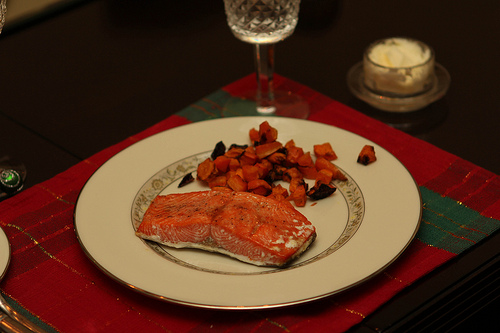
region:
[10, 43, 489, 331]
a placemat on the table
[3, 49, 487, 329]
the placemat is red and green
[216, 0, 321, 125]
a stemware glass on the placemat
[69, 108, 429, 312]
a plate on the placemat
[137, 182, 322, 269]
salmon on the plate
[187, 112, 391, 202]
orange vegetables on the plate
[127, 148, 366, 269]
flowers around the plate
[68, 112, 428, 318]
the plate has a gold rim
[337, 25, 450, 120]
a butter dish by the placemat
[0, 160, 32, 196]
a green mark on the placemat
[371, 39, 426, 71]
butter in the butter dish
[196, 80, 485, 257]
a green stripe on the placemat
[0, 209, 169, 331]
a gold stripe on the placemat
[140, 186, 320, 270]
the salmon is orange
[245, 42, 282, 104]
a stem on the glass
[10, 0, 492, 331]
the table is brown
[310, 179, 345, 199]
a black piece of squash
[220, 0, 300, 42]
a pattern on the glass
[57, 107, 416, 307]
the plate is round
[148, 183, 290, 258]
lines on the salmon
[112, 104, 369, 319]
food on a plate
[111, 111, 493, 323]
food on a white plate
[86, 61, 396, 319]
a plate on a table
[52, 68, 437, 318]
a white plate on a table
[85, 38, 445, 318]
a table with a white plate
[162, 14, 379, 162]
a glass on a table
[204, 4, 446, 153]
a clear glass on a table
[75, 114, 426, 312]
salmon and sweet potatoes on a plate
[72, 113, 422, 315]
fine china plate with gold rim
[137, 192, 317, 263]
a piece of salmon on a plate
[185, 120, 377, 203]
sweet potato chunks on a plate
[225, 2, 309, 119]
crystal wine glass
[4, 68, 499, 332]
a red and green placemat under the dish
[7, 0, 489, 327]
a black dinner table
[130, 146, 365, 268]
painted circle on the china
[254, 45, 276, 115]
stem of the crystal wine glass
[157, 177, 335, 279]
pink salmon on plate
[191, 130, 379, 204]
red vegetable on plate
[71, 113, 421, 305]
plate is white and round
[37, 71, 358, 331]
cloth is under plate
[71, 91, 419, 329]
cloth on brown table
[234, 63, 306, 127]
round base on glass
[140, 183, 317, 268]
salmon rests on plate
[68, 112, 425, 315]
plate underneath salmon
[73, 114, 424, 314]
plate is white and round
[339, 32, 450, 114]
butter disn near plate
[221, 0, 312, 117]
glass behind plate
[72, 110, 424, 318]
plate in front of glass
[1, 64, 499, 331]
placemat beneath white plate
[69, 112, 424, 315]
white plate on top of palce mat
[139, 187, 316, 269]
piece of baked pink salmon